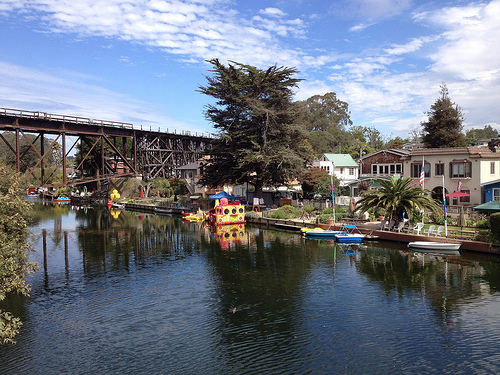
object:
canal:
[3, 201, 499, 374]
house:
[357, 149, 409, 188]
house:
[480, 179, 499, 205]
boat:
[206, 198, 247, 225]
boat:
[407, 241, 463, 251]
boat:
[304, 226, 348, 240]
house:
[313, 153, 360, 190]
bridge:
[2, 107, 223, 192]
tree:
[423, 81, 465, 150]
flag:
[419, 167, 424, 189]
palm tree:
[349, 171, 443, 229]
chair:
[384, 219, 396, 231]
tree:
[195, 58, 310, 198]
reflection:
[27, 220, 222, 287]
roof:
[324, 153, 359, 167]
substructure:
[1, 131, 217, 186]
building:
[398, 146, 498, 224]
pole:
[420, 156, 426, 223]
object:
[109, 189, 120, 201]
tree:
[1, 169, 36, 344]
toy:
[208, 198, 246, 225]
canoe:
[405, 238, 463, 252]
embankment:
[37, 184, 499, 258]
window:
[451, 161, 472, 178]